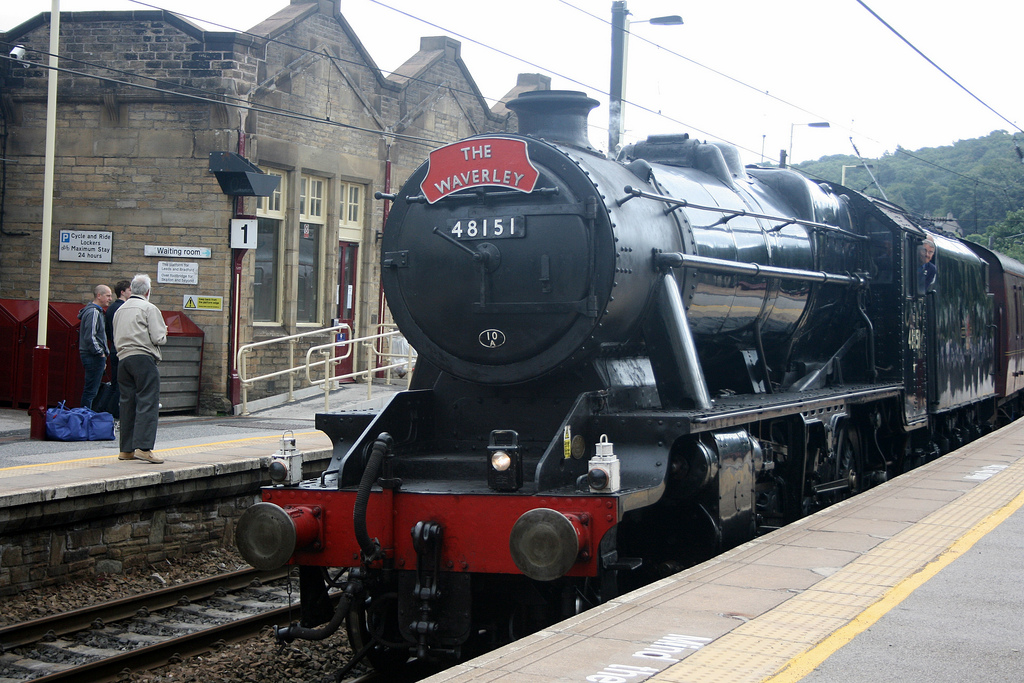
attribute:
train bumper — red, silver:
[237, 467, 623, 584]